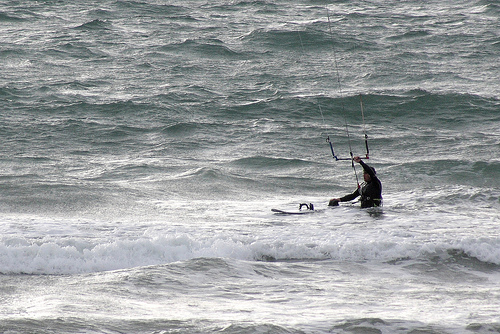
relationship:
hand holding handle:
[329, 197, 339, 203] [295, 195, 343, 211]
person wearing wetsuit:
[330, 156, 383, 208] [346, 164, 391, 213]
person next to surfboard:
[335, 156, 386, 210] [270, 202, 331, 216]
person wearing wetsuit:
[330, 156, 383, 208] [339, 160, 383, 209]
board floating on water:
[271, 197, 340, 214] [0, 0, 499, 330]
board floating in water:
[264, 192, 343, 224] [176, 103, 496, 271]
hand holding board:
[329, 190, 335, 204] [270, 193, 330, 214]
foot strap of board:
[298, 198, 313, 210] [273, 200, 342, 208]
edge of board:
[270, 207, 281, 214] [263, 202, 343, 213]